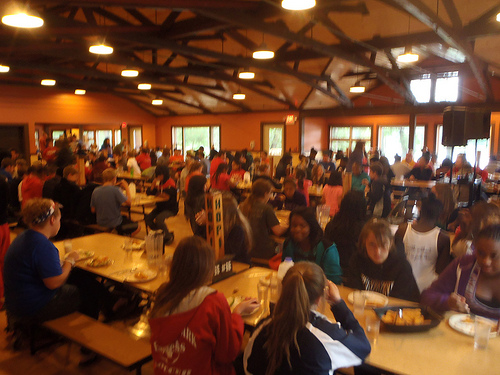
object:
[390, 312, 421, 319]
food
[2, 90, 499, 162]
wall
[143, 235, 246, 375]
girl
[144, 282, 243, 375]
hoodie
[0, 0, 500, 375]
cafeteria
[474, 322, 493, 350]
cup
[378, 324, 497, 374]
table top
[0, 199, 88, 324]
girl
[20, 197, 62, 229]
hair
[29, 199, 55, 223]
fabric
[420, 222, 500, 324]
girl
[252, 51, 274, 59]
light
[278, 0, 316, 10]
light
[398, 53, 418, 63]
light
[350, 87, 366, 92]
light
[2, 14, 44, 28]
light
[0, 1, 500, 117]
ceiling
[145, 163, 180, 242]
boy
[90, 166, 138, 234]
boy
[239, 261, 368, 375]
girl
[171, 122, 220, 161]
window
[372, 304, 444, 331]
bowl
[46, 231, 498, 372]
table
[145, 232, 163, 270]
water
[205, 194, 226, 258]
hop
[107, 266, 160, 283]
white plate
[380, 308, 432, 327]
lunch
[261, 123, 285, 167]
door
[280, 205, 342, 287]
girl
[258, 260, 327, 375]
hair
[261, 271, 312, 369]
ponytail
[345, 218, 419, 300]
girl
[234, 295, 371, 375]
jacket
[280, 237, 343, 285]
jacket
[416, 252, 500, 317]
jacket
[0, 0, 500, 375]
room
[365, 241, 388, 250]
glasses